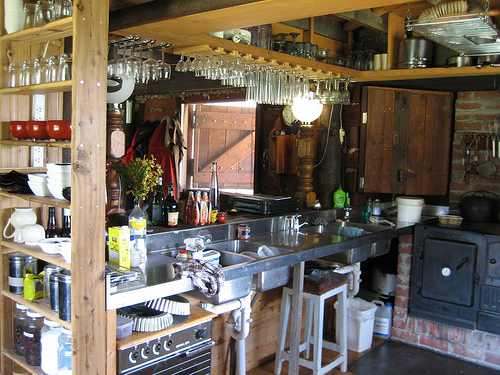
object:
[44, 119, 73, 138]
dishes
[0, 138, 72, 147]
shelf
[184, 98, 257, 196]
window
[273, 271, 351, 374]
stool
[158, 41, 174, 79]
glasses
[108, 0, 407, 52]
ceiling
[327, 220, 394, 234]
sink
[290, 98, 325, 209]
lamp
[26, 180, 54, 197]
dishes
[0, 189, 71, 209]
shelf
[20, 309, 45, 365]
jar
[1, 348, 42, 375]
shelf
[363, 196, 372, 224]
soap dispenser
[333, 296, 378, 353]
trashcan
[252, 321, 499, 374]
floor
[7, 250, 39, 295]
canisters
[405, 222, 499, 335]
oven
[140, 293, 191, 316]
pans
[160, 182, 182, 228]
bottles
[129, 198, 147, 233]
counter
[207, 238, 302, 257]
sinks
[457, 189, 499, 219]
pot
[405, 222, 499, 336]
stove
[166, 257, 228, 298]
towel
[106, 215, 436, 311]
counter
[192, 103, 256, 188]
door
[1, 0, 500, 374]
kitchen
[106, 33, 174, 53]
rack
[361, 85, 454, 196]
cupboard door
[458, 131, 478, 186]
utensils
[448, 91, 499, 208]
wall